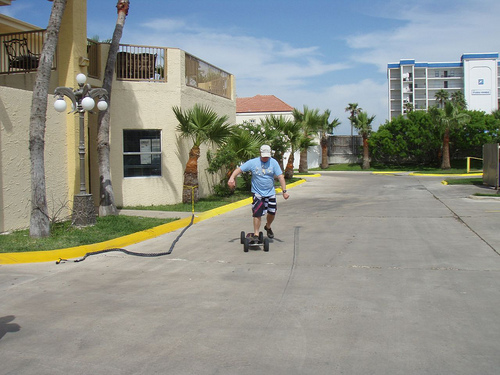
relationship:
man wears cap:
[226, 145, 292, 243] [260, 141, 271, 160]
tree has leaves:
[171, 103, 235, 204] [173, 102, 234, 144]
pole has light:
[53, 86, 113, 227] [54, 99, 69, 113]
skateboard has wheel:
[239, 229, 269, 252] [240, 229, 248, 244]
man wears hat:
[226, 145, 292, 243] [261, 144, 273, 159]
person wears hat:
[225, 144, 289, 238] [261, 144, 273, 159]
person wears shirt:
[225, 144, 289, 238] [239, 158, 283, 199]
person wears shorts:
[225, 144, 289, 238] [252, 192, 277, 217]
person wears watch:
[225, 144, 289, 238] [280, 187, 289, 195]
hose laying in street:
[55, 187, 196, 266] [2, 172, 498, 374]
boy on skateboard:
[225, 144, 290, 236] [239, 229, 269, 252]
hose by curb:
[55, 187, 196, 266] [1, 181, 301, 266]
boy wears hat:
[225, 144, 290, 236] [261, 144, 273, 159]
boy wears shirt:
[225, 144, 290, 236] [239, 158, 283, 199]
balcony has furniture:
[1, 30, 235, 96] [2, 37, 198, 82]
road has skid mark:
[1, 172, 499, 375] [283, 223, 307, 293]